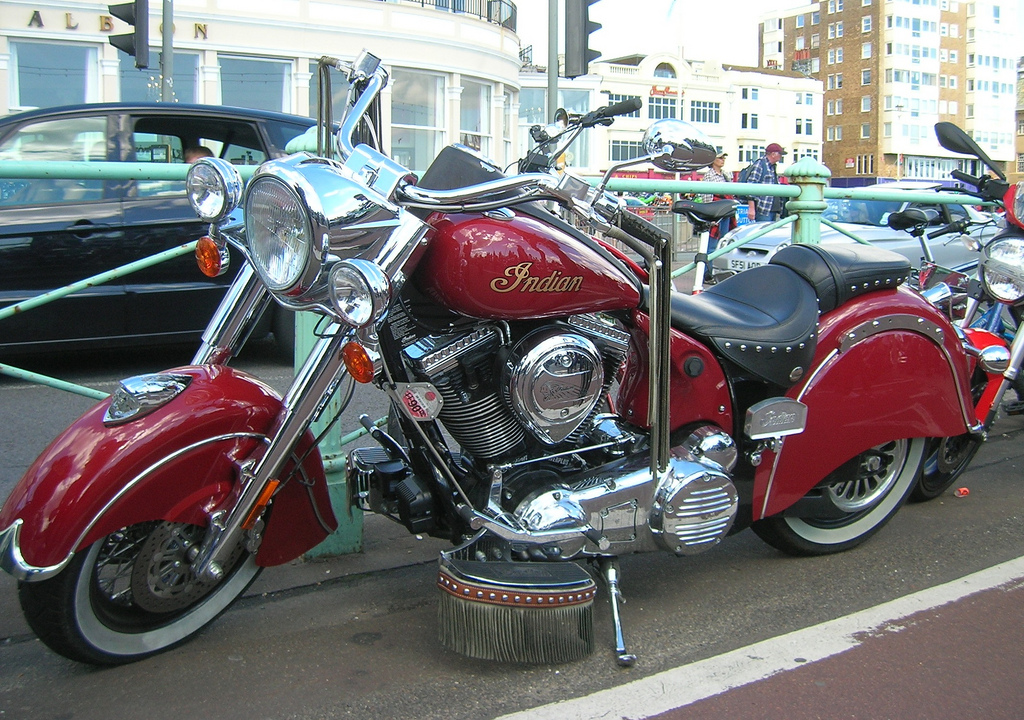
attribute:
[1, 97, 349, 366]
car — black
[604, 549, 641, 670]
kickstand — chrome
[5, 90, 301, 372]
vehicles — parked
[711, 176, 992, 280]
vehicles — parked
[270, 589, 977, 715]
road — alongside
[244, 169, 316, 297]
headlight — large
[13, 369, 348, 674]
wheel — black, white, red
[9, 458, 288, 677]
tire — black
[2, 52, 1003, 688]
bike — red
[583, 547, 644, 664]
kick stand — silver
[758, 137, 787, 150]
baseball cap — red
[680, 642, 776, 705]
line — white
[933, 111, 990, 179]
mirror — black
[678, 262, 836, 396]
seat — black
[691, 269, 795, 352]
seat — black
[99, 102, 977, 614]
motorcycle — red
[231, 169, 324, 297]
headlight — chrome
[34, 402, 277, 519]
fender — red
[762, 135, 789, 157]
hat — red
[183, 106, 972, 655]
motorcycle — chrome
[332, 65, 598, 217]
handle bars — chrome